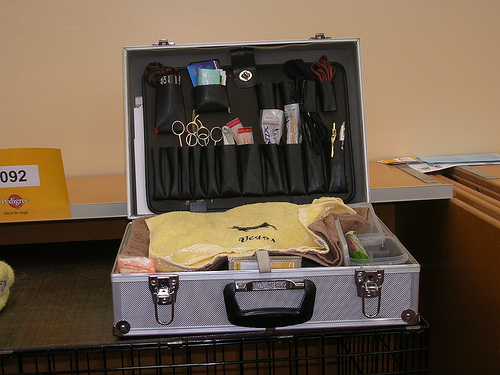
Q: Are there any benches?
A: No, there are no benches.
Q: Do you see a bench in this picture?
A: No, there are no benches.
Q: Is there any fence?
A: No, there are no fences.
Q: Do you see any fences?
A: No, there are no fences.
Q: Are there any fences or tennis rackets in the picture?
A: No, there are no fences or tennis rackets.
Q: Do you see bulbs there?
A: No, there are no bulbs.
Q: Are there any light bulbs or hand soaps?
A: No, there are no light bulbs or hand soaps.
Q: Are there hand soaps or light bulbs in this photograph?
A: No, there are no light bulbs or hand soaps.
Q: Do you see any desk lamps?
A: No, there are no desk lamps.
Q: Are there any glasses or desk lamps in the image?
A: No, there are no desk lamps or glasses.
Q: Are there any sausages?
A: No, there are no sausages.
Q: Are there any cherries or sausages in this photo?
A: No, there are no sausages or cherries.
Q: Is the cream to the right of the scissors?
A: Yes, the cream is to the right of the scissors.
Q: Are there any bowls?
A: No, there are no bowls.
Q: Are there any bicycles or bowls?
A: No, there are no bowls or bicycles.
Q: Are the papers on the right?
A: Yes, the papers are on the right of the image.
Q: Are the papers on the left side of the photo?
A: No, the papers are on the right of the image.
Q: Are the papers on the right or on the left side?
A: The papers are on the right of the image.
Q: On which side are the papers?
A: The papers are on the right of the image.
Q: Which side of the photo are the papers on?
A: The papers are on the right of the image.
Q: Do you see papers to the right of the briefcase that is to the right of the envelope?
A: Yes, there are papers to the right of the brief case.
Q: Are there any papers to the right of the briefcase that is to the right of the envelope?
A: Yes, there are papers to the right of the brief case.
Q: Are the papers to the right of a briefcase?
A: Yes, the papers are to the right of a briefcase.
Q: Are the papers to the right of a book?
A: No, the papers are to the right of a briefcase.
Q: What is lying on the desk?
A: The papers are lying on the desk.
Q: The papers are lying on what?
A: The papers are lying on the desk.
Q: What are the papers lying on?
A: The papers are lying on the desk.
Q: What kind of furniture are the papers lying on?
A: The papers are lying on the desk.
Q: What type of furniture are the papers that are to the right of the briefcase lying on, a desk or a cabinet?
A: The papers are lying on a desk.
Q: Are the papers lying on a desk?
A: Yes, the papers are lying on a desk.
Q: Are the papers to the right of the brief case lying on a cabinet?
A: No, the papers are lying on a desk.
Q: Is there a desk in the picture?
A: Yes, there is a desk.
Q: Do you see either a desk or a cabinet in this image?
A: Yes, there is a desk.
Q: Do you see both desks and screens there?
A: No, there is a desk but no screens.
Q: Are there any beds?
A: No, there are no beds.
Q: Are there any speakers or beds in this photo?
A: No, there are no beds or speakers.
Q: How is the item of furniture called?
A: The piece of furniture is a desk.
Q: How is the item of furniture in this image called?
A: The piece of furniture is a desk.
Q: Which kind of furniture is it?
A: The piece of furniture is a desk.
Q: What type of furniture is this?
A: That is a desk.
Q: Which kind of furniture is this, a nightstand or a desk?
A: That is a desk.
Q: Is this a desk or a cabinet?
A: This is a desk.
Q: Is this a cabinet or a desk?
A: This is a desk.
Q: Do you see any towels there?
A: Yes, there is a towel.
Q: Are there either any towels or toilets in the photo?
A: Yes, there is a towel.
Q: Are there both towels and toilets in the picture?
A: No, there is a towel but no toilets.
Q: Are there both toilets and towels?
A: No, there is a towel but no toilets.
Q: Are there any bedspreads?
A: No, there are no bedspreads.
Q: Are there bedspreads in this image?
A: No, there are no bedspreads.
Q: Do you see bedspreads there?
A: No, there are no bedspreads.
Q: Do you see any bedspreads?
A: No, there are no bedspreads.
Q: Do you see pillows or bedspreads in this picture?
A: No, there are no bedspreads or pillows.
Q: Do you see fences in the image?
A: No, there are no fences.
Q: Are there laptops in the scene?
A: No, there are no laptops.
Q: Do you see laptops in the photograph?
A: No, there are no laptops.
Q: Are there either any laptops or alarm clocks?
A: No, there are no laptops or alarm clocks.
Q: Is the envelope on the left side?
A: Yes, the envelope is on the left of the image.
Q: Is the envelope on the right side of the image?
A: No, the envelope is on the left of the image.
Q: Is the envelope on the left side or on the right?
A: The envelope is on the left of the image.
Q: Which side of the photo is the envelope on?
A: The envelope is on the left of the image.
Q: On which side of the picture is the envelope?
A: The envelope is on the left of the image.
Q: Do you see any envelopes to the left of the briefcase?
A: Yes, there is an envelope to the left of the briefcase.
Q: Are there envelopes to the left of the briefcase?
A: Yes, there is an envelope to the left of the briefcase.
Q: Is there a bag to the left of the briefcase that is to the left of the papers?
A: No, there is an envelope to the left of the briefcase.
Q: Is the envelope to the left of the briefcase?
A: Yes, the envelope is to the left of the briefcase.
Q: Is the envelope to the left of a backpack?
A: No, the envelope is to the left of the briefcase.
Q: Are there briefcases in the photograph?
A: Yes, there is a briefcase.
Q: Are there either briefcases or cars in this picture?
A: Yes, there is a briefcase.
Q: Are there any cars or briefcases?
A: Yes, there is a briefcase.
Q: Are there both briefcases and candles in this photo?
A: No, there is a briefcase but no candles.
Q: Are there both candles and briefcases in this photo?
A: No, there is a briefcase but no candles.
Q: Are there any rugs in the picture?
A: No, there are no rugs.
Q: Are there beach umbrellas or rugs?
A: No, there are no rugs or beach umbrellas.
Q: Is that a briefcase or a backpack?
A: That is a briefcase.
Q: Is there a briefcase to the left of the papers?
A: Yes, there is a briefcase to the left of the papers.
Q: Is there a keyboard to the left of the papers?
A: No, there is a briefcase to the left of the papers.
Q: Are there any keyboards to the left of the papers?
A: No, there is a briefcase to the left of the papers.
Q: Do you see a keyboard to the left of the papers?
A: No, there is a briefcase to the left of the papers.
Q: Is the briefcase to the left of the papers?
A: Yes, the briefcase is to the left of the papers.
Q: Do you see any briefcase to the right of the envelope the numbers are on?
A: Yes, there is a briefcase to the right of the envelope.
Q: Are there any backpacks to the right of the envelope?
A: No, there is a briefcase to the right of the envelope.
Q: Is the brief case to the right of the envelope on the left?
A: Yes, the brief case is to the right of the envelope.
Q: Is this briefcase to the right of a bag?
A: No, the briefcase is to the right of the envelope.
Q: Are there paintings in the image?
A: No, there are no paintings.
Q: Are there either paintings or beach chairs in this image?
A: No, there are no paintings or beach chairs.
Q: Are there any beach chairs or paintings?
A: No, there are no paintings or beach chairs.